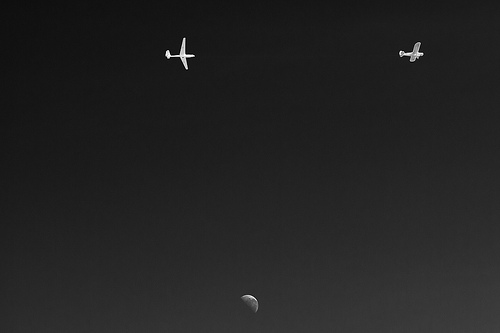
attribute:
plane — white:
[163, 36, 196, 73]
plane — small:
[164, 34, 194, 72]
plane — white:
[164, 34, 193, 67]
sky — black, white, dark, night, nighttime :
[7, 6, 482, 323]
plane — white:
[163, 32, 201, 74]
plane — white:
[399, 41, 424, 62]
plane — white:
[394, 40, 424, 66]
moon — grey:
[230, 291, 265, 319]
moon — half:
[232, 288, 261, 318]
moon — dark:
[237, 293, 266, 314]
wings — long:
[177, 31, 188, 73]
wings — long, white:
[175, 34, 190, 75]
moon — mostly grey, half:
[233, 289, 273, 320]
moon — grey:
[232, 283, 262, 323]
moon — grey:
[234, 287, 262, 318]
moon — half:
[236, 291, 266, 317]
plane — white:
[391, 39, 429, 69]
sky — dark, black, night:
[22, 20, 454, 322]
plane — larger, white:
[157, 30, 200, 74]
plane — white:
[390, 38, 430, 65]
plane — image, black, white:
[155, 22, 204, 72]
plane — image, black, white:
[396, 22, 437, 65]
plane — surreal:
[154, 33, 200, 79]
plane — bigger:
[160, 31, 199, 72]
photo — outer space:
[12, 22, 453, 320]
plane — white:
[396, 34, 422, 64]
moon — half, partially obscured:
[240, 294, 258, 314]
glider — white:
[164, 35, 196, 71]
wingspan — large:
[178, 37, 189, 70]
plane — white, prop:
[398, 40, 423, 61]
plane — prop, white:
[397, 40, 427, 62]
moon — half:
[238, 292, 258, 313]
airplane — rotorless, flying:
[165, 37, 195, 69]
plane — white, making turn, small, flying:
[398, 40, 425, 62]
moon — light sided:
[240, 293, 260, 313]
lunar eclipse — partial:
[241, 292, 258, 313]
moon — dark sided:
[239, 294, 257, 314]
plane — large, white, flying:
[166, 36, 196, 69]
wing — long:
[179, 33, 188, 53]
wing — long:
[180, 57, 190, 70]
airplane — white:
[164, 32, 197, 68]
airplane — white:
[399, 40, 424, 62]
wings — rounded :
[406, 40, 422, 61]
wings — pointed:
[182, 33, 192, 71]